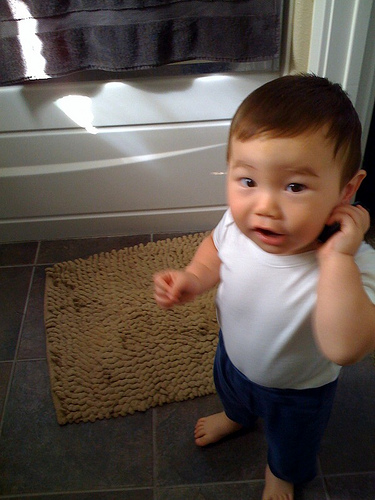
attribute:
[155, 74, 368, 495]
baby — little, cute, young, asian, boy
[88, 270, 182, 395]
mat — fuzzy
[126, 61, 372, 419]
boy — happy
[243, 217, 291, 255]
mouth — smiling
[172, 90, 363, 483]
baby — asian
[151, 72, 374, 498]
child — barefoot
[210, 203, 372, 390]
shirt — white 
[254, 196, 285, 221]
nose — small 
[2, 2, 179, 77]
towel — navy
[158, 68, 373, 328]
baby — cute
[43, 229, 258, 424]
rug — tan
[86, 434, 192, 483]
tile — dark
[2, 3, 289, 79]
towel — grey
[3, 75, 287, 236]
tub — white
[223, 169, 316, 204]
eyes — cute, clear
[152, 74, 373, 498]
boy — baby, standing, young, asian, little